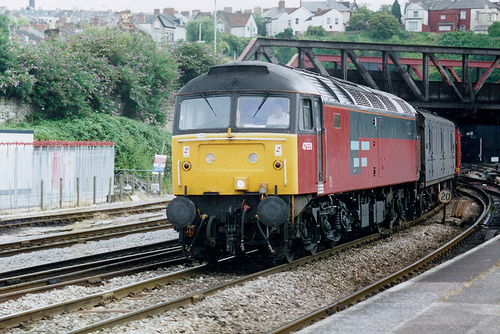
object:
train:
[162, 61, 460, 268]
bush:
[35, 117, 154, 140]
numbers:
[437, 188, 453, 204]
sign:
[437, 189, 454, 224]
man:
[266, 102, 291, 129]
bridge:
[236, 36, 499, 109]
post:
[40, 178, 44, 211]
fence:
[1, 169, 170, 217]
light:
[233, 176, 248, 190]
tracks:
[37, 241, 184, 319]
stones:
[220, 288, 286, 328]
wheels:
[284, 196, 356, 255]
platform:
[300, 231, 500, 334]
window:
[178, 94, 295, 132]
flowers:
[82, 54, 121, 100]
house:
[263, 8, 345, 35]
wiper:
[253, 89, 270, 117]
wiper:
[195, 87, 220, 116]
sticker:
[302, 142, 313, 152]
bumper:
[167, 194, 293, 228]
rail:
[323, 126, 327, 185]